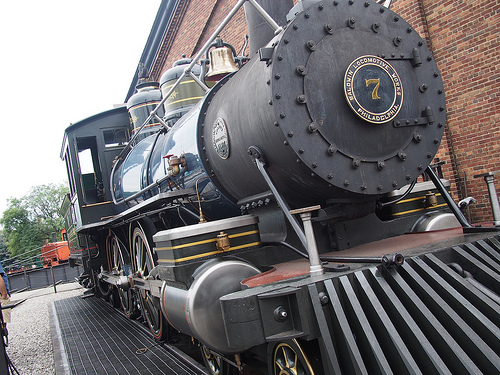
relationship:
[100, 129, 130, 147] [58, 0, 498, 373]
window on train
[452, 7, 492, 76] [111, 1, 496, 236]
bricks on building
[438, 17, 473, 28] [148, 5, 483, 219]
brick on wall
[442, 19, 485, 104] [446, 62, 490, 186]
brick in wall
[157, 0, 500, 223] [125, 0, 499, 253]
wall on building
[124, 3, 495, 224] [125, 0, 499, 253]
wall on building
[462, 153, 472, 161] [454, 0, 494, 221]
brick in wall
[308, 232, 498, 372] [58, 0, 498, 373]
cattle guard on train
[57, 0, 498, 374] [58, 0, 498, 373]
train engine on train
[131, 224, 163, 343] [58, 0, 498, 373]
wheel on train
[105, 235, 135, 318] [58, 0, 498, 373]
wheel on train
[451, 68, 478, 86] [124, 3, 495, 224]
brick in a wall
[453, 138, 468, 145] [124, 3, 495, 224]
brick in a wall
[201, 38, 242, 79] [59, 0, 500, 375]
bell on train engine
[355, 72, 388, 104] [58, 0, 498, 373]
number seven on train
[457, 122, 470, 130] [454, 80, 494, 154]
brick in wall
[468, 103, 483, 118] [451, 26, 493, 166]
brick in wall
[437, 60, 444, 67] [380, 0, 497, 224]
brick in wall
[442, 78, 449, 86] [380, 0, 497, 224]
brick in wall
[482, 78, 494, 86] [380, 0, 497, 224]
brick in wall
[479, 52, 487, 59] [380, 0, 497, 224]
brick in wall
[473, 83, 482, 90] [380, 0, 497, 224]
brick in wall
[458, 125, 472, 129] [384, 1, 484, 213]
brick in wall